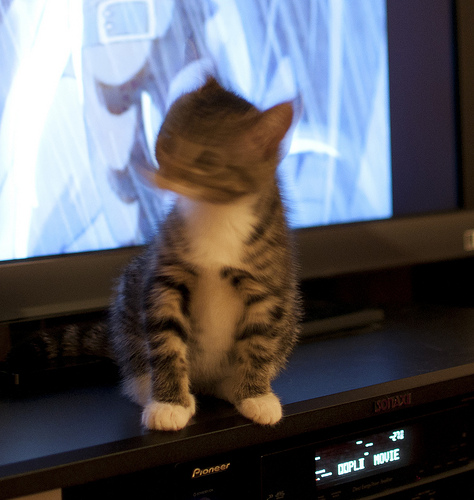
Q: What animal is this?
A: Cat.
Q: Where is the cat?
A: On the entertainment center.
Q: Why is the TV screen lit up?
A: Turned on.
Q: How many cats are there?
A: 1.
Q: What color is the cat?
A: Brown, black and white.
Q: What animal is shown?
A: A cat.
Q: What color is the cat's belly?
A: White.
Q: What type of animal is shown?
A: A tabby cat.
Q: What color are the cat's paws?
A: White.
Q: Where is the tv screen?
A: Behind the cat.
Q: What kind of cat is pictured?
A: A tabby.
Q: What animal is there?
A: Cat.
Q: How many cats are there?
A: 1.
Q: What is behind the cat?
A: Television.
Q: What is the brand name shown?
A: Pioneer.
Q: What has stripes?
A: Cat.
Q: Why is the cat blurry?
A: In motion.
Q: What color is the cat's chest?
A: White.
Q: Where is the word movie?
A: Front of DVD player.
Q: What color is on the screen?
A: Mostly blue.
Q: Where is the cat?
A: Sitting on a shelf.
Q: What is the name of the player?
A: Pioneer.